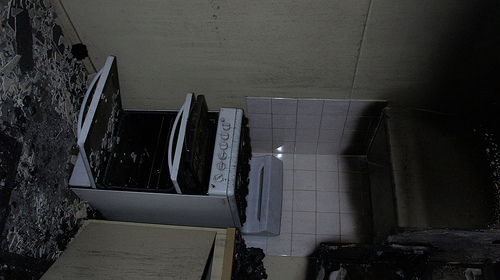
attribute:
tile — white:
[248, 96, 355, 151]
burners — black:
[236, 122, 263, 212]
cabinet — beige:
[38, 217, 236, 279]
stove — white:
[58, 59, 294, 206]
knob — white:
[186, 123, 248, 158]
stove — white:
[95, 89, 290, 210]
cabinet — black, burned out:
[313, 200, 445, 279]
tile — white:
[314, 169, 339, 191]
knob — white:
[219, 119, 238, 132]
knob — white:
[212, 172, 223, 183]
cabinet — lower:
[21, 192, 241, 278]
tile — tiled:
[293, 166, 320, 196]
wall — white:
[242, 100, 409, 262]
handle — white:
[69, 59, 110, 136]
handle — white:
[167, 103, 184, 172]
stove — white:
[67, 52, 284, 236]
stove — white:
[85, 70, 234, 207]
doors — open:
[199, 191, 286, 231]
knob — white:
[215, 150, 240, 163]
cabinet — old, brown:
[29, 213, 326, 279]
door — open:
[30, 220, 217, 279]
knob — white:
[220, 130, 229, 139]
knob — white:
[219, 140, 229, 149]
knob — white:
[219, 148, 226, 159]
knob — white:
[217, 157, 226, 171]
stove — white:
[66, 103, 288, 236]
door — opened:
[73, 54, 219, 199]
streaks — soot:
[50, 241, 221, 279]